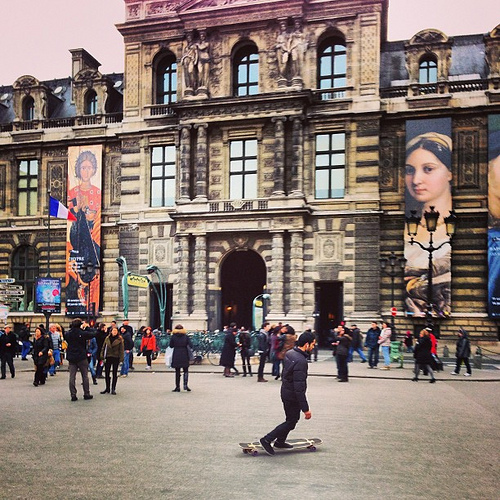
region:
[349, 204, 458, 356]
black lamp post with three lamps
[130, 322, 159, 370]
person in a red jacket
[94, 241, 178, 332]
tall green light poles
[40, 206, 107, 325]
large orange and black piece of art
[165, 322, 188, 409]
woman in a black jacket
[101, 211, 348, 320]
large opening in stone building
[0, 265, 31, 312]
lots of street signs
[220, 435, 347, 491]
black and white skate board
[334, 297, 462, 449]
ghroup of people on side walk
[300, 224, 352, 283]
decorative squre stone art work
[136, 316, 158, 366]
person wearing red coat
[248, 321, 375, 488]
guy riding on skateboard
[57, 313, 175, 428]
people standing on pavement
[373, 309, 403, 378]
person wearing blue pants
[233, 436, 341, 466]
black and white skateboard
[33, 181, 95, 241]
red, white, and blue flag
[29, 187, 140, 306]
flag on pole in front of building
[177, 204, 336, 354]
large entrance to building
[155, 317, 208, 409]
person carrying white bag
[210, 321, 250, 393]
person wearing black coat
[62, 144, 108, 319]
a two story banner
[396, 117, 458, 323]
a two story banner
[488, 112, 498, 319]
a two story banner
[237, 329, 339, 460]
a man on skateboard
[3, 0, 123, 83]
a pink overcast sky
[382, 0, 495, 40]
a pink overcast sky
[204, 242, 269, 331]
an arched entryway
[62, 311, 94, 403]
a person standing in plaza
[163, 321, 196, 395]
a person standing in plaza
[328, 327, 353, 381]
a person standing in plaza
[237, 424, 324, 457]
A long skate board.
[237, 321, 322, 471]
A man rides a longboard.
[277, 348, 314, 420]
A puffy black jacket.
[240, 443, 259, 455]
The wheels are purple.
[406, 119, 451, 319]
A banner with art.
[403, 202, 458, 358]
A street lamp.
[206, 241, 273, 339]
Archway to the building.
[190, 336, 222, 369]
A bike on the curb.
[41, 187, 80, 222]
A french flag waving.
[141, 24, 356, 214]
A set of large windows.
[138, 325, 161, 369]
person wearing red jacket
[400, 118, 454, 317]
long banner on large stone building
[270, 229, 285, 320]
stone column near doorway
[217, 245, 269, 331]
large arched doorway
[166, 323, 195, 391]
person wearing a black coat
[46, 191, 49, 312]
black metal flagpole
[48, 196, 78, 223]
flag on flagpole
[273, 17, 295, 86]
stone caryatid on building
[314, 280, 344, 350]
small rectangular doorway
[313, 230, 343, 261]
square decorative element above doorway